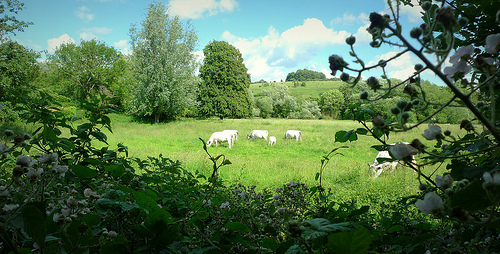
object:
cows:
[246, 129, 269, 142]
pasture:
[56, 117, 468, 203]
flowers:
[26, 167, 44, 184]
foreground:
[5, 144, 492, 253]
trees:
[45, 39, 125, 116]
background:
[0, 0, 488, 116]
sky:
[3, 0, 492, 81]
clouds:
[228, 20, 353, 78]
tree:
[127, 1, 195, 126]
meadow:
[249, 82, 341, 96]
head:
[203, 140, 212, 149]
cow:
[205, 131, 234, 150]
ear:
[377, 167, 382, 170]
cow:
[367, 142, 418, 181]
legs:
[226, 139, 232, 149]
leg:
[215, 141, 219, 148]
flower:
[389, 141, 418, 160]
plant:
[329, 3, 500, 253]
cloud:
[166, 1, 232, 20]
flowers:
[444, 59, 472, 81]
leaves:
[213, 96, 224, 102]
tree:
[193, 39, 251, 120]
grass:
[82, 116, 472, 201]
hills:
[244, 81, 356, 101]